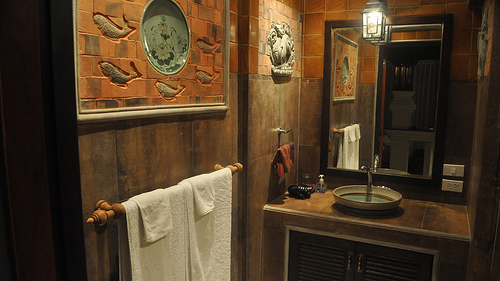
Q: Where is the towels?
A: Hanging on the bar.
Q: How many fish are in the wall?
A: 5.